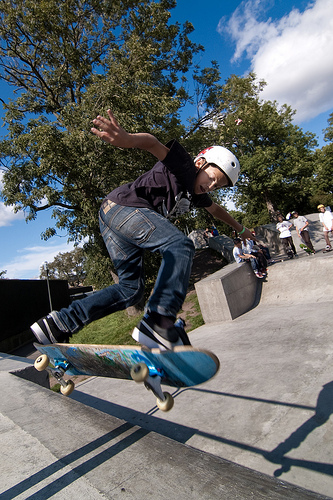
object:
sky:
[0, 0, 332, 282]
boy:
[233, 238, 266, 279]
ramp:
[3, 255, 332, 490]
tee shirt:
[276, 221, 292, 239]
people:
[241, 238, 268, 273]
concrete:
[219, 269, 331, 436]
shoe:
[256, 273, 264, 279]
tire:
[130, 363, 149, 384]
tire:
[156, 391, 173, 412]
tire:
[34, 354, 48, 372]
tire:
[60, 380, 74, 396]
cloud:
[261, 32, 303, 89]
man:
[291, 211, 316, 254]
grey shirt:
[294, 215, 308, 234]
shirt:
[100, 139, 213, 223]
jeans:
[57, 199, 195, 333]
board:
[32, 342, 220, 411]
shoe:
[131, 311, 191, 349]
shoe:
[30, 310, 70, 344]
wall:
[225, 270, 254, 316]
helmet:
[193, 145, 240, 187]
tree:
[0, 1, 233, 298]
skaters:
[317, 203, 332, 250]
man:
[30, 108, 259, 351]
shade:
[106, 401, 199, 447]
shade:
[202, 430, 247, 451]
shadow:
[26, 438, 116, 484]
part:
[155, 399, 163, 408]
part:
[215, 436, 227, 440]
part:
[142, 370, 148, 378]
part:
[141, 421, 148, 435]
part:
[167, 361, 173, 371]